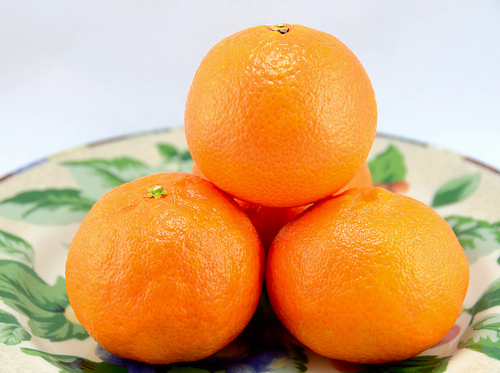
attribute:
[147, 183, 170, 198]
stem — small, green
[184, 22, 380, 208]
fruit — orange, smooth, balancing, sitting, stacked, round, whole, small, ripe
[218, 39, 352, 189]
peel — shiny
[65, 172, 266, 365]
fruit — smooth, shiny, orange, bright, stacked, whole, round, green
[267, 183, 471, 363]
fruit — smooth, bright, stacked, whole, round, citrus, pitted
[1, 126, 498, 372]
plate — round, designed, white, decorative, floral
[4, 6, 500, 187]
background — white, plain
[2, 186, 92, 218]
leaf — green, painted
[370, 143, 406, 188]
leaf — green, painted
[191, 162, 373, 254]
orange — behind, shiny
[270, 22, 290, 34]
nub — green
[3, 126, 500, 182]
edge — blue, dark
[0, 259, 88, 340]
leaf — large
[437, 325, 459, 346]
flower — pink